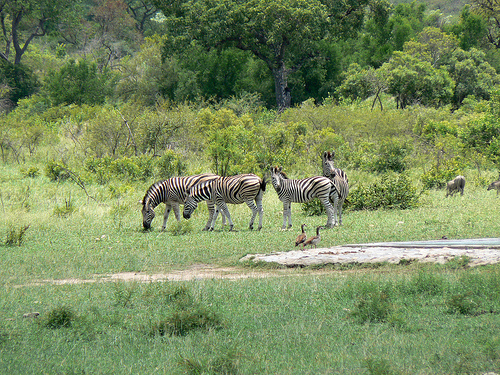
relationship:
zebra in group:
[314, 146, 357, 232] [132, 144, 365, 241]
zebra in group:
[269, 156, 348, 234] [132, 144, 365, 241]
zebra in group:
[175, 171, 271, 236] [132, 144, 365, 241]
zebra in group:
[135, 171, 224, 236] [132, 144, 365, 241]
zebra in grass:
[314, 146, 357, 232] [0, 163, 499, 374]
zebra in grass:
[269, 156, 348, 234] [0, 163, 499, 374]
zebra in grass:
[175, 171, 271, 236] [0, 163, 499, 374]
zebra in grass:
[135, 171, 224, 236] [0, 163, 499, 374]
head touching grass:
[136, 201, 160, 236] [0, 163, 499, 374]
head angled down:
[136, 201, 160, 236] [136, 201, 162, 234]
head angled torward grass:
[136, 201, 160, 236] [0, 163, 499, 374]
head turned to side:
[265, 164, 291, 197] [264, 160, 290, 198]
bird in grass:
[291, 218, 311, 253] [0, 163, 499, 374]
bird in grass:
[301, 222, 330, 257] [0, 163, 499, 374]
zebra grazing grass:
[135, 171, 224, 236] [0, 163, 499, 374]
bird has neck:
[291, 218, 311, 253] [298, 226, 307, 236]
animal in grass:
[437, 174, 472, 204] [0, 163, 499, 374]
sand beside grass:
[9, 259, 311, 299] [0, 163, 499, 374]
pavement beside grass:
[236, 233, 499, 273] [0, 163, 499, 374]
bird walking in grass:
[291, 218, 311, 253] [0, 163, 499, 374]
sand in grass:
[9, 259, 311, 299] [0, 163, 499, 374]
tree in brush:
[161, 0, 376, 115] [1, 1, 498, 184]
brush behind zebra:
[1, 1, 498, 184] [314, 146, 357, 232]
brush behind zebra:
[1, 1, 498, 184] [269, 156, 348, 234]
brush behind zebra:
[1, 1, 498, 184] [175, 171, 271, 236]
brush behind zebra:
[1, 1, 498, 184] [135, 171, 224, 236]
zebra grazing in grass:
[434, 170, 471, 200] [0, 163, 499, 374]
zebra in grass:
[434, 170, 471, 200] [0, 163, 499, 374]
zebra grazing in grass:
[135, 171, 224, 236] [0, 163, 499, 374]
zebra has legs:
[269, 156, 348, 234] [274, 202, 342, 232]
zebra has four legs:
[269, 156, 348, 234] [274, 202, 342, 232]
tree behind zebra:
[161, 0, 376, 115] [314, 146, 357, 232]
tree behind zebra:
[120, 2, 169, 46] [269, 156, 348, 234]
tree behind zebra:
[5, 2, 61, 99] [175, 171, 271, 236]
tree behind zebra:
[371, 22, 500, 114] [175, 171, 271, 236]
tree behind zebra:
[371, 22, 500, 114] [434, 170, 471, 200]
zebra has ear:
[314, 146, 357, 232] [317, 151, 328, 162]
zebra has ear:
[314, 146, 357, 232] [328, 151, 340, 162]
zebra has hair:
[135, 171, 224, 236] [141, 172, 169, 212]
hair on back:
[141, 172, 169, 212] [143, 167, 212, 209]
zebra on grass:
[314, 146, 357, 232] [0, 163, 499, 374]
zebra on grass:
[269, 156, 348, 234] [0, 163, 499, 374]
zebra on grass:
[175, 171, 271, 236] [0, 163, 499, 374]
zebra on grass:
[135, 171, 224, 236] [0, 163, 499, 374]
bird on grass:
[291, 218, 311, 253] [0, 163, 499, 374]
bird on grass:
[301, 222, 330, 257] [0, 163, 499, 374]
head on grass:
[136, 201, 160, 236] [0, 163, 499, 374]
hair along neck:
[141, 172, 169, 212] [298, 226, 307, 236]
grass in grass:
[0, 163, 499, 374] [0, 163, 499, 374]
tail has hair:
[330, 181, 354, 202] [334, 195, 347, 203]